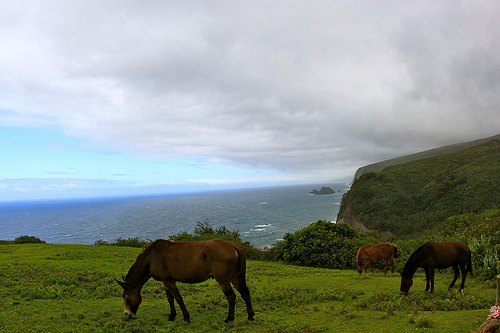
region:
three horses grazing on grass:
[124, 223, 477, 331]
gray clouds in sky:
[290, 53, 402, 127]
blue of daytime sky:
[12, 132, 64, 169]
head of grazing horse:
[110, 283, 149, 328]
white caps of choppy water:
[241, 215, 280, 242]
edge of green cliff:
[336, 168, 383, 219]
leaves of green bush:
[292, 223, 348, 268]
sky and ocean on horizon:
[164, 183, 225, 202]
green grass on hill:
[267, 264, 328, 284]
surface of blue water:
[69, 202, 135, 222]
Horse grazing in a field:
[97, 228, 267, 330]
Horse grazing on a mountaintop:
[121, 232, 261, 332]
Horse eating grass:
[112, 234, 265, 331]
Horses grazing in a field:
[107, 211, 480, 330]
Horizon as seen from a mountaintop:
[7, 179, 335, 211]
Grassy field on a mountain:
[21, 248, 115, 329]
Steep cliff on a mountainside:
[331, 143, 382, 242]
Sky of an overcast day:
[232, 19, 405, 149]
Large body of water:
[57, 203, 282, 238]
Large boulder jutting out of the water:
[297, 179, 344, 206]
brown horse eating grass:
[120, 237, 255, 329]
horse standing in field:
[116, 239, 256, 327]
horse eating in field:
[396, 241, 477, 295]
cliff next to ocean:
[340, 144, 499, 236]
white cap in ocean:
[251, 218, 273, 234]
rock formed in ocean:
[313, 183, 334, 196]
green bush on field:
[271, 223, 388, 271]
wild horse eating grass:
[353, 237, 400, 277]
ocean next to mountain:
[6, 185, 346, 246]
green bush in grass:
[14, 233, 47, 247]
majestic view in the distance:
[25, 107, 322, 242]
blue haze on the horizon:
[23, 186, 210, 218]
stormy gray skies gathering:
[136, 53, 350, 148]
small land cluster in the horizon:
[298, 167, 353, 204]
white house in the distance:
[240, 211, 292, 236]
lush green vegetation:
[283, 209, 380, 263]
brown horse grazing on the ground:
[101, 225, 291, 325]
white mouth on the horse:
[112, 299, 160, 323]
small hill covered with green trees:
[323, 153, 443, 214]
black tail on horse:
[230, 241, 269, 302]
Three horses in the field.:
[61, 183, 473, 308]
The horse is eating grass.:
[102, 238, 297, 325]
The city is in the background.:
[116, 164, 321, 226]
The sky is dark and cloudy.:
[115, 48, 378, 134]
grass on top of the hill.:
[336, 152, 477, 215]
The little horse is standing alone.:
[326, 220, 386, 278]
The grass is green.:
[28, 223, 131, 306]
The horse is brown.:
[381, 246, 491, 323]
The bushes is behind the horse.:
[249, 211, 359, 266]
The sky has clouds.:
[181, 23, 423, 140]